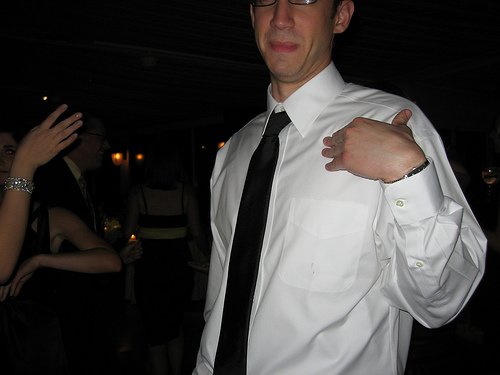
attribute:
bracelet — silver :
[4, 172, 41, 200]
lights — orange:
[104, 144, 148, 166]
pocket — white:
[278, 190, 372, 294]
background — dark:
[4, 2, 499, 369]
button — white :
[397, 199, 403, 206]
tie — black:
[213, 110, 290, 373]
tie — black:
[217, 106, 302, 371]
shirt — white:
[195, 82, 486, 328]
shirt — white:
[194, 57, 487, 372]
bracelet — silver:
[11, 169, 48, 209]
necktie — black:
[203, 102, 283, 374]